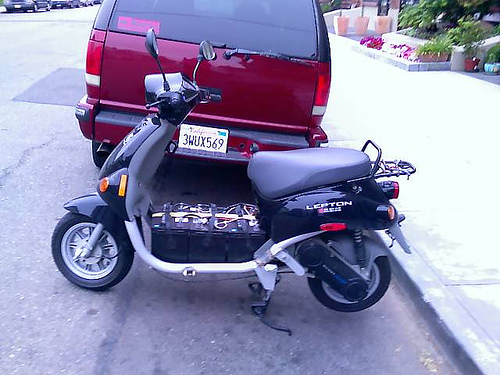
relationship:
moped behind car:
[51, 27, 416, 336] [74, 0, 332, 168]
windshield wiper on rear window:
[224, 48, 310, 64] [102, 2, 322, 62]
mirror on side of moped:
[196, 40, 218, 63] [51, 27, 416, 336]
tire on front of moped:
[49, 203, 139, 292] [50, 28, 419, 338]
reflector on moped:
[311, 218, 357, 236] [51, 58, 406, 373]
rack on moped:
[366, 157, 413, 183] [50, 28, 419, 338]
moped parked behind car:
[51, 27, 416, 336] [117, 1, 382, 152]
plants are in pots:
[417, 16, 488, 56] [417, 51, 483, 76]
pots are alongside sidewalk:
[417, 51, 483, 76] [319, 0, 481, 369]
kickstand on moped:
[246, 277, 293, 336] [51, 27, 416, 336]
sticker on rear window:
[113, 13, 163, 37] [107, 0, 319, 61]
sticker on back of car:
[113, 13, 163, 37] [71, 3, 337, 190]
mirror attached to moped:
[142, 25, 172, 88] [51, 27, 416, 336]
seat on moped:
[246, 147, 372, 200] [51, 27, 416, 336]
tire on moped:
[51, 211, 136, 292] [51, 27, 416, 336]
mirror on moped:
[196, 40, 218, 63] [51, 27, 416, 336]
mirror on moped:
[142, 25, 160, 58] [51, 27, 416, 336]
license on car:
[177, 120, 236, 158] [74, 0, 332, 168]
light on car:
[83, 35, 105, 75] [74, 0, 332, 168]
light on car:
[80, 70, 104, 87] [74, 0, 332, 168]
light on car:
[311, 70, 332, 107] [74, 0, 332, 168]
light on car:
[307, 102, 327, 117] [74, 0, 332, 168]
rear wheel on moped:
[309, 235, 393, 307] [50, 28, 419, 338]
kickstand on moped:
[245, 277, 300, 339] [50, 28, 419, 338]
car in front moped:
[74, 0, 332, 168] [50, 28, 419, 338]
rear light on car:
[83, 38, 103, 89] [74, 0, 332, 168]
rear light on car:
[310, 71, 329, 118] [74, 0, 332, 168]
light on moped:
[95, 177, 110, 192] [55, 28, 230, 297]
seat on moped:
[246, 144, 376, 200] [50, 28, 419, 338]